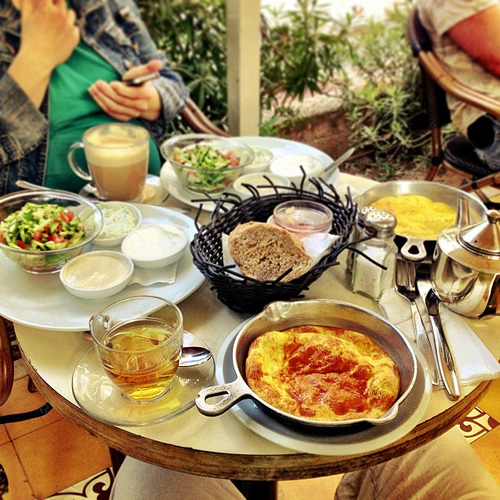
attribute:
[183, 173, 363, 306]
basket — black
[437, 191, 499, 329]
kettle — silver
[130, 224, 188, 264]
dressing — white